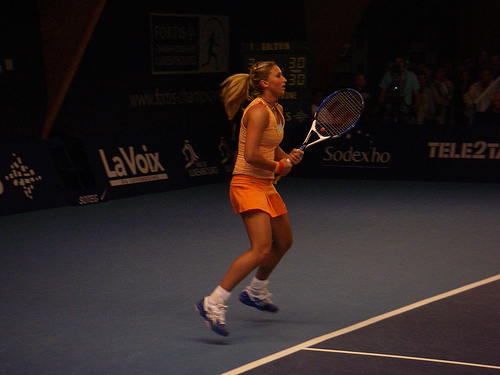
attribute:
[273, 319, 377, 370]
lines — white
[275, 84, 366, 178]
tennis racket — blue , white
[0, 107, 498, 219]
wall — black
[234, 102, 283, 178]
shirt — orange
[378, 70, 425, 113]
shirt — blue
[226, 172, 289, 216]
skirt — orange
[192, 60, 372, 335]
woman — orange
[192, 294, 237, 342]
shoe — blue, white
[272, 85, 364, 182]
racket — blue, white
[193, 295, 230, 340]
trim — blue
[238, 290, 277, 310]
trim — blue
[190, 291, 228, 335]
shoe — white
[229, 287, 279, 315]
shoe — white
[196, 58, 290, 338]
woman — airborne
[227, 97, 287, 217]
tennis outfit — orange